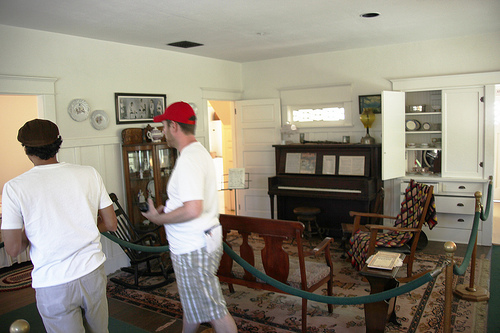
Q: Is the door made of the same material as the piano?
A: Yes, both the door and the piano are made of wood.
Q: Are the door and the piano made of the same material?
A: Yes, both the door and the piano are made of wood.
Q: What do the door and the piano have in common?
A: The material, both the door and the piano are wooden.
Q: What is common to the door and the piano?
A: The material, both the door and the piano are wooden.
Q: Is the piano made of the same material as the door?
A: Yes, both the piano and the door are made of wood.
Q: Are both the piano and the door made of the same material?
A: Yes, both the piano and the door are made of wood.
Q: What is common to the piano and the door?
A: The material, both the piano and the door are wooden.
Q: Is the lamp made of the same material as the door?
A: No, the lamp is made of glass and the door is made of wood.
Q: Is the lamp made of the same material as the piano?
A: No, the lamp is made of glass and the piano is made of wood.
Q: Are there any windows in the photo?
A: Yes, there is a window.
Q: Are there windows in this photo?
A: Yes, there is a window.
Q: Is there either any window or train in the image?
A: Yes, there is a window.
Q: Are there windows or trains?
A: Yes, there is a window.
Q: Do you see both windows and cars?
A: No, there is a window but no cars.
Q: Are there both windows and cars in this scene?
A: No, there is a window but no cars.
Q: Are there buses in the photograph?
A: No, there are no buses.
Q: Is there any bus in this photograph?
A: No, there are no buses.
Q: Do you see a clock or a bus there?
A: No, there are no buses or clocks.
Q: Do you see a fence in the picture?
A: No, there are no fences.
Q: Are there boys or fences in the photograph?
A: No, there are no fences or boys.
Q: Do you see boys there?
A: No, there are no boys.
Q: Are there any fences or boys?
A: No, there are no boys or fences.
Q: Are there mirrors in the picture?
A: No, there are no mirrors.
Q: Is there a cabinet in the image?
A: Yes, there is a cabinet.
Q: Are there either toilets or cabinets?
A: Yes, there is a cabinet.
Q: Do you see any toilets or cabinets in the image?
A: Yes, there is a cabinet.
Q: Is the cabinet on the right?
A: Yes, the cabinet is on the right of the image.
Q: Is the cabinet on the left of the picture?
A: No, the cabinet is on the right of the image.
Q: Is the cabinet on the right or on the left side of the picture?
A: The cabinet is on the right of the image.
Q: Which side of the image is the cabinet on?
A: The cabinet is on the right of the image.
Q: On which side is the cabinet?
A: The cabinet is on the right of the image.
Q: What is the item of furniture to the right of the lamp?
A: The piece of furniture is a cabinet.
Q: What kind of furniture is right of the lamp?
A: The piece of furniture is a cabinet.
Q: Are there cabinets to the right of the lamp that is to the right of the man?
A: Yes, there is a cabinet to the right of the lamp.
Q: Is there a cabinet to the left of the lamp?
A: No, the cabinet is to the right of the lamp.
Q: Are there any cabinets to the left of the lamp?
A: No, the cabinet is to the right of the lamp.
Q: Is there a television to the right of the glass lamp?
A: No, there is a cabinet to the right of the lamp.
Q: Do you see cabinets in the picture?
A: Yes, there is a cabinet.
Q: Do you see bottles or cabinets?
A: Yes, there is a cabinet.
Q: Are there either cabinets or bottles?
A: Yes, there is a cabinet.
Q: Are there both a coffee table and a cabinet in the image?
A: No, there is a cabinet but no coffee tables.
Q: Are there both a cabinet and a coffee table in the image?
A: No, there is a cabinet but no coffee tables.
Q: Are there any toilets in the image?
A: No, there are no toilets.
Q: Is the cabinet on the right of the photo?
A: Yes, the cabinet is on the right of the image.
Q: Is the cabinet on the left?
A: No, the cabinet is on the right of the image.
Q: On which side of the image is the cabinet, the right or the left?
A: The cabinet is on the right of the image.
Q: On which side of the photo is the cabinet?
A: The cabinet is on the right of the image.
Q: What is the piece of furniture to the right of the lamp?
A: The piece of furniture is a cabinet.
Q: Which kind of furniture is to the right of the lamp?
A: The piece of furniture is a cabinet.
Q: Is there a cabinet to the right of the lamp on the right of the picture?
A: Yes, there is a cabinet to the right of the lamp.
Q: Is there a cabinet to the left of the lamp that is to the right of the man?
A: No, the cabinet is to the right of the lamp.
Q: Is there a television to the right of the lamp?
A: No, there is a cabinet to the right of the lamp.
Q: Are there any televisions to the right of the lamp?
A: No, there is a cabinet to the right of the lamp.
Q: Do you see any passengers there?
A: No, there are no passengers.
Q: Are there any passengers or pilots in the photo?
A: No, there are no passengers or pilots.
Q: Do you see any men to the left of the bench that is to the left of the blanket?
A: Yes, there is a man to the left of the bench.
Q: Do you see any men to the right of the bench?
A: No, the man is to the left of the bench.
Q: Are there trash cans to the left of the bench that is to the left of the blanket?
A: No, there is a man to the left of the bench.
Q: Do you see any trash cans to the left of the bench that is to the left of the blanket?
A: No, there is a man to the left of the bench.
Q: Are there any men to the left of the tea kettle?
A: Yes, there is a man to the left of the tea kettle.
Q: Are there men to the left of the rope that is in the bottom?
A: Yes, there is a man to the left of the rope.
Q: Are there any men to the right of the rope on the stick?
A: No, the man is to the left of the rope.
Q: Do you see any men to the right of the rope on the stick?
A: No, the man is to the left of the rope.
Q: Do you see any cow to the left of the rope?
A: No, there is a man to the left of the rope.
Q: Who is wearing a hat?
A: The man is wearing a hat.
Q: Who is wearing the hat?
A: The man is wearing a hat.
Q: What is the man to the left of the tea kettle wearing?
A: The man is wearing a hat.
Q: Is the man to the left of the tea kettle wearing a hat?
A: Yes, the man is wearing a hat.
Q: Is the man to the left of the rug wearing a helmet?
A: No, the man is wearing a hat.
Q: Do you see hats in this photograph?
A: Yes, there is a hat.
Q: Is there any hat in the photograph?
A: Yes, there is a hat.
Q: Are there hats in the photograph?
A: Yes, there is a hat.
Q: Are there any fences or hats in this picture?
A: Yes, there is a hat.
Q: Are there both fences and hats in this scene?
A: No, there is a hat but no fences.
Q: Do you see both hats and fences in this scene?
A: No, there is a hat but no fences.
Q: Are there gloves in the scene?
A: No, there are no gloves.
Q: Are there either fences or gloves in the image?
A: No, there are no gloves or fences.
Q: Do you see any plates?
A: Yes, there is a plate.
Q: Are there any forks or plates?
A: Yes, there is a plate.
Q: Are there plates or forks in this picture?
A: Yes, there is a plate.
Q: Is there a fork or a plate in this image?
A: Yes, there is a plate.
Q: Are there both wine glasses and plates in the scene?
A: No, there is a plate but no wine glasses.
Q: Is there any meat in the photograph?
A: No, there is no meat.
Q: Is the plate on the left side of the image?
A: Yes, the plate is on the left of the image.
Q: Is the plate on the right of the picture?
A: No, the plate is on the left of the image.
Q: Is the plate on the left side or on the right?
A: The plate is on the left of the image.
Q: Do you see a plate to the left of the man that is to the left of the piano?
A: Yes, there is a plate to the left of the man.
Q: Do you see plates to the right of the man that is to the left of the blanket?
A: No, the plate is to the left of the man.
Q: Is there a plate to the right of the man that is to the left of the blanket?
A: No, the plate is to the left of the man.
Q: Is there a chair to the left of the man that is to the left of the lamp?
A: No, there is a plate to the left of the man.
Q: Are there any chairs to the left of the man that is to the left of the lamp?
A: No, there is a plate to the left of the man.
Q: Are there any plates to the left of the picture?
A: Yes, there is a plate to the left of the picture.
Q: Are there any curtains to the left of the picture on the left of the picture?
A: No, there is a plate to the left of the picture.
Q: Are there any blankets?
A: Yes, there is a blanket.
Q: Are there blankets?
A: Yes, there is a blanket.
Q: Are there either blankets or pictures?
A: Yes, there is a blanket.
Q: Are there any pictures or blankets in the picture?
A: Yes, there is a blanket.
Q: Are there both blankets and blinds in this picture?
A: No, there is a blanket but no blinds.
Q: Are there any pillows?
A: No, there are no pillows.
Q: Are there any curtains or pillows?
A: No, there are no pillows or curtains.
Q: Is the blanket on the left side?
A: No, the blanket is on the right of the image.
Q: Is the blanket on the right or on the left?
A: The blanket is on the right of the image.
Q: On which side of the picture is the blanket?
A: The blanket is on the right of the image.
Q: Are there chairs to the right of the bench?
A: No, there is a blanket to the right of the bench.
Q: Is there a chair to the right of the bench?
A: No, there is a blanket to the right of the bench.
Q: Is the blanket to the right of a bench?
A: Yes, the blanket is to the right of a bench.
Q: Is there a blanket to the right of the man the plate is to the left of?
A: Yes, there is a blanket to the right of the man.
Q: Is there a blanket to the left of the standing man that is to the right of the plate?
A: No, the blanket is to the right of the man.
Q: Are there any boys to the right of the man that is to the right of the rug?
A: No, there is a blanket to the right of the man.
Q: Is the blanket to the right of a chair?
A: No, the blanket is to the right of a man.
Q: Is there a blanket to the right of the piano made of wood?
A: Yes, there is a blanket to the right of the piano.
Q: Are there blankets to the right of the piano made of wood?
A: Yes, there is a blanket to the right of the piano.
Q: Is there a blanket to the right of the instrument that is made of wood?
A: Yes, there is a blanket to the right of the piano.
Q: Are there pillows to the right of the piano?
A: No, there is a blanket to the right of the piano.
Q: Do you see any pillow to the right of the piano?
A: No, there is a blanket to the right of the piano.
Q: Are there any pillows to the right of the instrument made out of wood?
A: No, there is a blanket to the right of the piano.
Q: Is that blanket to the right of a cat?
A: No, the blanket is to the right of the piano.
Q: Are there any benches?
A: Yes, there is a bench.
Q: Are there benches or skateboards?
A: Yes, there is a bench.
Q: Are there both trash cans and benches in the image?
A: No, there is a bench but no trash cans.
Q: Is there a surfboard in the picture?
A: No, there are no surfboards.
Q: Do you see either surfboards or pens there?
A: No, there are no surfboards or pens.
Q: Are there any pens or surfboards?
A: No, there are no surfboards or pens.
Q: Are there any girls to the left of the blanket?
A: No, there is a bench to the left of the blanket.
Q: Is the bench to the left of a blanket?
A: Yes, the bench is to the left of a blanket.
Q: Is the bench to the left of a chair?
A: No, the bench is to the left of a blanket.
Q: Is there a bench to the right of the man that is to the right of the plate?
A: Yes, there is a bench to the right of the man.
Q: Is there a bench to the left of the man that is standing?
A: No, the bench is to the right of the man.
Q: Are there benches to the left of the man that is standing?
A: No, the bench is to the right of the man.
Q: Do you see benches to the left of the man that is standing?
A: No, the bench is to the right of the man.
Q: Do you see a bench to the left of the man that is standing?
A: No, the bench is to the right of the man.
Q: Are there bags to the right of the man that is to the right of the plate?
A: No, there is a bench to the right of the man.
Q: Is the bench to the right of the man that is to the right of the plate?
A: Yes, the bench is to the right of the man.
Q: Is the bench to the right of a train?
A: No, the bench is to the right of the man.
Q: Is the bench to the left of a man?
A: No, the bench is to the right of a man.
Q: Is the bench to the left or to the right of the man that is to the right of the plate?
A: The bench is to the right of the man.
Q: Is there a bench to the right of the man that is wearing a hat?
A: Yes, there is a bench to the right of the man.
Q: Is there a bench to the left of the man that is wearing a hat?
A: No, the bench is to the right of the man.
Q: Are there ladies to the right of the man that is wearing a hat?
A: No, there is a bench to the right of the man.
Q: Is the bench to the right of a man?
A: Yes, the bench is to the right of a man.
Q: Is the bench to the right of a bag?
A: No, the bench is to the right of a man.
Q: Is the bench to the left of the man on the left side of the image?
A: No, the bench is to the right of the man.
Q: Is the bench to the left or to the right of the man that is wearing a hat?
A: The bench is to the right of the man.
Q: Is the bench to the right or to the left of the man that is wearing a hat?
A: The bench is to the right of the man.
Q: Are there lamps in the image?
A: Yes, there is a lamp.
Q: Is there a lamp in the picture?
A: Yes, there is a lamp.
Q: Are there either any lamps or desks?
A: Yes, there is a lamp.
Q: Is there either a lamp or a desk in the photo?
A: Yes, there is a lamp.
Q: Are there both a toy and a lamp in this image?
A: No, there is a lamp but no toys.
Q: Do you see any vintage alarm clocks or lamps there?
A: Yes, there is a vintage lamp.